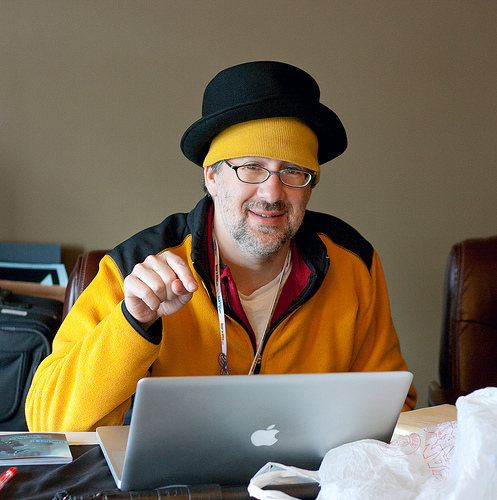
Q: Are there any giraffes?
A: No, there are no giraffes.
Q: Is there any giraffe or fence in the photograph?
A: No, there are no giraffes or fences.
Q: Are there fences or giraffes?
A: No, there are no giraffes or fences.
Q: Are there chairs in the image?
A: Yes, there is a chair.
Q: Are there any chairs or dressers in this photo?
A: Yes, there is a chair.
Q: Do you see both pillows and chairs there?
A: No, there is a chair but no pillows.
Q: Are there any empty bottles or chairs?
A: Yes, there is an empty chair.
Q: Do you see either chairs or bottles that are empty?
A: Yes, the chair is empty.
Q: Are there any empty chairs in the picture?
A: Yes, there is an empty chair.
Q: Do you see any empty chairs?
A: Yes, there is an empty chair.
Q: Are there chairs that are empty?
A: Yes, there is a chair that is empty.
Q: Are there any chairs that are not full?
A: Yes, there is a empty chair.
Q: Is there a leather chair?
A: Yes, there is a chair that is made of leather.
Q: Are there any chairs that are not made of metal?
A: Yes, there is a chair that is made of leather.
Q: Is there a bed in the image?
A: No, there are no beds.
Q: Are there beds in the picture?
A: No, there are no beds.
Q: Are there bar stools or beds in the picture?
A: No, there are no beds or bar stools.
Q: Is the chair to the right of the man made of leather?
A: Yes, the chair is made of leather.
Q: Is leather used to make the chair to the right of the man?
A: Yes, the chair is made of leather.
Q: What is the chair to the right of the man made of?
A: The chair is made of leather.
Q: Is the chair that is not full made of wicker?
A: No, the chair is made of leather.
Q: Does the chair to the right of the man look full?
A: No, the chair is empty.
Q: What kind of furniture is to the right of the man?
A: The piece of furniture is a chair.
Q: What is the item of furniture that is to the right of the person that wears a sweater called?
A: The piece of furniture is a chair.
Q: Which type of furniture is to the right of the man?
A: The piece of furniture is a chair.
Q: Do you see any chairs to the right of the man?
A: Yes, there is a chair to the right of the man.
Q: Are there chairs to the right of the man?
A: Yes, there is a chair to the right of the man.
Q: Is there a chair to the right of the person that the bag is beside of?
A: Yes, there is a chair to the right of the man.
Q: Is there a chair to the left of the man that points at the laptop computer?
A: No, the chair is to the right of the man.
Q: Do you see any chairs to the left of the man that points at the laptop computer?
A: No, the chair is to the right of the man.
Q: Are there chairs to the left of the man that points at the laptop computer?
A: No, the chair is to the right of the man.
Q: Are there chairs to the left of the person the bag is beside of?
A: No, the chair is to the right of the man.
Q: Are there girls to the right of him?
A: No, there is a chair to the right of the man.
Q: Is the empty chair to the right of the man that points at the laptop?
A: Yes, the chair is to the right of the man.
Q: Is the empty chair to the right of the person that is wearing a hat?
A: Yes, the chair is to the right of the man.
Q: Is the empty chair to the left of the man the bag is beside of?
A: No, the chair is to the right of the man.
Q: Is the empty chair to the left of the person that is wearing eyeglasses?
A: No, the chair is to the right of the man.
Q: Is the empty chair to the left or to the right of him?
A: The chair is to the right of the man.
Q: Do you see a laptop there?
A: Yes, there is a laptop.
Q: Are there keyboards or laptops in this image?
A: Yes, there is a laptop.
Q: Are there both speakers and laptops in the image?
A: No, there is a laptop but no speakers.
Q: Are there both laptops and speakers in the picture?
A: No, there is a laptop but no speakers.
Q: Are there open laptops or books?
A: Yes, there is an open laptop.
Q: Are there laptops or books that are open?
A: Yes, the laptop is open.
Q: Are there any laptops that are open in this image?
A: Yes, there is an open laptop.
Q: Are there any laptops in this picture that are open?
A: Yes, there is a laptop that is open.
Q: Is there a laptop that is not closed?
A: Yes, there is a open laptop.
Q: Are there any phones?
A: No, there are no phones.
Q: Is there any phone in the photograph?
A: No, there are no phones.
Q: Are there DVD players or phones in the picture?
A: No, there are no phones or DVD players.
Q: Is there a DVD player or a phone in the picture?
A: No, there are no phones or DVD players.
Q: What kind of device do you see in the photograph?
A: The device is a laptop.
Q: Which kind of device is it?
A: The device is a laptop.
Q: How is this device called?
A: This is a laptop.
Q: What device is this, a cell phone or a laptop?
A: This is a laptop.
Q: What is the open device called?
A: The device is a laptop.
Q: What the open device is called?
A: The device is a laptop.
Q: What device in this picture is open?
A: The device is a laptop.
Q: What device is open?
A: The device is a laptop.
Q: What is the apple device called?
A: The device is a laptop.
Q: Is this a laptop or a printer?
A: This is a laptop.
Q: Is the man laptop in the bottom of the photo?
A: Yes, the laptop is in the bottom of the image.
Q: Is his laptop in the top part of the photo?
A: No, the laptop is in the bottom of the image.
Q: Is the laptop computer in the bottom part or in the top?
A: The laptop computer is in the bottom of the image.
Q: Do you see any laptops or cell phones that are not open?
A: No, there is a laptop but it is open.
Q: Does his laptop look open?
A: Yes, the laptop is open.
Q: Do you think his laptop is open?
A: Yes, the laptop is open.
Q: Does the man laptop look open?
A: Yes, the laptop computer is open.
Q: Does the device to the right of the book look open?
A: Yes, the laptop computer is open.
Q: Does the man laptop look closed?
A: No, the laptop is open.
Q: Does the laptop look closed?
A: No, the laptop is open.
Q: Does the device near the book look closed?
A: No, the laptop is open.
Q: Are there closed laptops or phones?
A: No, there is a laptop but it is open.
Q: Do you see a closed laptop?
A: No, there is a laptop but it is open.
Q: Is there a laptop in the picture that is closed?
A: No, there is a laptop but it is open.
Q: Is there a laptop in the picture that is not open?
A: No, there is a laptop but it is open.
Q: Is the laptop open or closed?
A: The laptop is open.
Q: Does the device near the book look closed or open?
A: The laptop is open.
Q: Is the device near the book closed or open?
A: The laptop is open.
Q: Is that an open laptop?
A: Yes, that is an open laptop.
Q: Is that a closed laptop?
A: No, that is an open laptop.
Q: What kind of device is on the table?
A: The device is a laptop.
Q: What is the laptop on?
A: The laptop is on the table.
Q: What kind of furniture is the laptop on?
A: The laptop is on the table.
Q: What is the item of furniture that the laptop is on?
A: The piece of furniture is a table.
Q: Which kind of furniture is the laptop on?
A: The laptop is on the table.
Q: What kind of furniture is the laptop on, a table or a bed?
A: The laptop is on a table.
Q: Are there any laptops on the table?
A: Yes, there is a laptop on the table.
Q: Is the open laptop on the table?
A: Yes, the laptop is on the table.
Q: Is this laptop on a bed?
A: No, the laptop is on the table.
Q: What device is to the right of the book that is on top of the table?
A: The device is a laptop.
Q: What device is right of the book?
A: The device is a laptop.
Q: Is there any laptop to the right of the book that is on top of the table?
A: Yes, there is a laptop to the right of the book.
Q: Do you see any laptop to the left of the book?
A: No, the laptop is to the right of the book.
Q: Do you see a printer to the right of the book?
A: No, there is a laptop to the right of the book.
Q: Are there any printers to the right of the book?
A: No, there is a laptop to the right of the book.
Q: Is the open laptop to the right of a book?
A: Yes, the laptop is to the right of a book.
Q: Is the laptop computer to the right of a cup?
A: No, the laptop computer is to the right of a book.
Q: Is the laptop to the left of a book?
A: No, the laptop is to the right of a book.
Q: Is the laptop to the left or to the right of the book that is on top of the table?
A: The laptop is to the right of the book.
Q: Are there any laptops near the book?
A: Yes, there is a laptop near the book.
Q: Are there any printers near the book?
A: No, there is a laptop near the book.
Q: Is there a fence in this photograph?
A: No, there are no fences.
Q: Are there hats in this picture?
A: Yes, there is a hat.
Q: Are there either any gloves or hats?
A: Yes, there is a hat.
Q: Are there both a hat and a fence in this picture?
A: No, there is a hat but no fences.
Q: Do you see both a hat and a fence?
A: No, there is a hat but no fences.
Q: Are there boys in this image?
A: No, there are no boys.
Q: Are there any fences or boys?
A: No, there are no boys or fences.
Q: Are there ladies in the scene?
A: No, there are no ladies.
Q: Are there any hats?
A: Yes, there is a hat.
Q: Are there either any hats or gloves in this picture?
A: Yes, there is a hat.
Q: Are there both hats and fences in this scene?
A: No, there is a hat but no fences.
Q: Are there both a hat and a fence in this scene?
A: No, there is a hat but no fences.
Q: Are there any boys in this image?
A: No, there are no boys.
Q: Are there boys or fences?
A: No, there are no boys or fences.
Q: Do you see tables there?
A: Yes, there is a table.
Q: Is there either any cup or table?
A: Yes, there is a table.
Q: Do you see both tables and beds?
A: No, there is a table but no beds.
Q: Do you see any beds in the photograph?
A: No, there are no beds.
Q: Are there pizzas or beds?
A: No, there are no beds or pizzas.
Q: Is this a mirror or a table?
A: This is a table.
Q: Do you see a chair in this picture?
A: Yes, there is a chair.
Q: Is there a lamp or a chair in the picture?
A: Yes, there is a chair.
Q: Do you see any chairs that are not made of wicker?
A: Yes, there is a chair that is made of leather.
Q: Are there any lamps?
A: No, there are no lamps.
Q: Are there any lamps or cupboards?
A: No, there are no lamps or cupboards.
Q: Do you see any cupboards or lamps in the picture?
A: No, there are no lamps or cupboards.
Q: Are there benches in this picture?
A: No, there are no benches.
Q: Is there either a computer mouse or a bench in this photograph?
A: No, there are no benches or computer mice.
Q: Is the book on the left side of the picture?
A: Yes, the book is on the left of the image.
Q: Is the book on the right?
A: No, the book is on the left of the image.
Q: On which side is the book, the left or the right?
A: The book is on the left of the image.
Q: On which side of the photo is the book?
A: The book is on the left of the image.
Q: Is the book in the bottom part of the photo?
A: Yes, the book is in the bottom of the image.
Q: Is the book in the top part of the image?
A: No, the book is in the bottom of the image.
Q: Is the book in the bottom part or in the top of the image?
A: The book is in the bottom of the image.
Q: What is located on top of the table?
A: The book is on top of the table.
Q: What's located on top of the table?
A: The book is on top of the table.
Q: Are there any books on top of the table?
A: Yes, there is a book on top of the table.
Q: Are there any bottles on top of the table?
A: No, there is a book on top of the table.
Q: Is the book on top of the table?
A: Yes, the book is on top of the table.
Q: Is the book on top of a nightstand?
A: No, the book is on top of the table.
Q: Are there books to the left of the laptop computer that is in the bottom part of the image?
A: Yes, there is a book to the left of the laptop.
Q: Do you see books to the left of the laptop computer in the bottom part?
A: Yes, there is a book to the left of the laptop.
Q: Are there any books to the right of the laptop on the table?
A: No, the book is to the left of the laptop.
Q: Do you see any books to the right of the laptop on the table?
A: No, the book is to the left of the laptop.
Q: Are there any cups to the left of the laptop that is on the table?
A: No, there is a book to the left of the laptop.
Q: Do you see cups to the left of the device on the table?
A: No, there is a book to the left of the laptop.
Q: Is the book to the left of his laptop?
A: Yes, the book is to the left of the laptop computer.